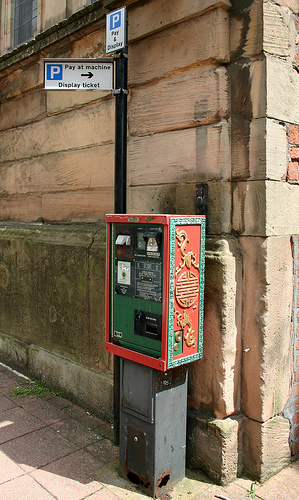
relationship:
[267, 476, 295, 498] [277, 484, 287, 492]
cement tile on ground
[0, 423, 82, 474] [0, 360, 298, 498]
cement tile on ground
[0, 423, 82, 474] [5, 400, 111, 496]
cement tile on ground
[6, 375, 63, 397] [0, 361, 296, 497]
weeds growing sidewalk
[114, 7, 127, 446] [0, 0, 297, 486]
pole against building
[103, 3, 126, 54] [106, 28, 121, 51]
sign with words